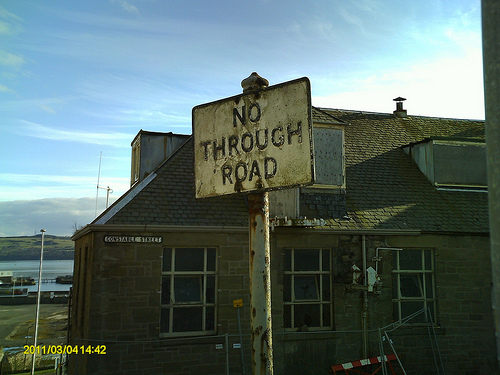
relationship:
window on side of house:
[162, 243, 215, 335] [70, 107, 500, 371]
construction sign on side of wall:
[332, 348, 402, 375] [86, 231, 498, 375]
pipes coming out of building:
[376, 304, 446, 371] [70, 107, 500, 371]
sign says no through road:
[194, 76, 317, 200] [202, 103, 303, 185]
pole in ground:
[247, 188, 273, 375] [4, 362, 500, 371]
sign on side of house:
[104, 233, 160, 244] [70, 107, 500, 371]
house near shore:
[70, 107, 500, 371] [4, 271, 66, 298]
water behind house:
[1, 258, 82, 293] [70, 107, 500, 371]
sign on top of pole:
[194, 76, 317, 200] [247, 188, 273, 375]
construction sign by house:
[332, 348, 402, 375] [70, 107, 500, 371]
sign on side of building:
[104, 233, 160, 244] [70, 107, 500, 371]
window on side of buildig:
[162, 243, 215, 335] [70, 107, 500, 371]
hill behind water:
[5, 232, 75, 260] [1, 258, 82, 293]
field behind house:
[3, 303, 69, 345] [70, 107, 500, 371]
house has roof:
[70, 107, 500, 371] [88, 104, 488, 228]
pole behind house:
[32, 229, 41, 375] [70, 107, 500, 371]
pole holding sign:
[247, 188, 273, 375] [194, 76, 317, 200]